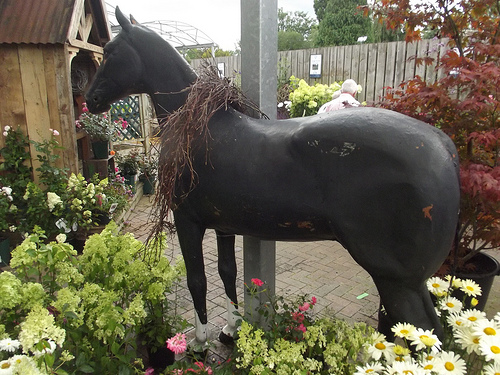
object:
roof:
[0, 0, 112, 46]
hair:
[341, 79, 358, 94]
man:
[316, 79, 360, 114]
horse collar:
[150, 61, 260, 269]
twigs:
[150, 139, 184, 177]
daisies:
[369, 271, 498, 373]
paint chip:
[423, 203, 432, 219]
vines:
[138, 70, 243, 256]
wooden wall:
[3, 46, 74, 193]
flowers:
[166, 332, 188, 357]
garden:
[1, 115, 499, 374]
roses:
[1, 120, 56, 240]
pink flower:
[252, 278, 264, 287]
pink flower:
[297, 302, 311, 311]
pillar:
[239, 1, 278, 318]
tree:
[379, 3, 496, 273]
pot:
[444, 247, 498, 307]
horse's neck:
[159, 70, 247, 136]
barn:
[0, 0, 118, 199]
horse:
[85, 6, 462, 355]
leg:
[176, 208, 209, 323]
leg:
[215, 225, 243, 331]